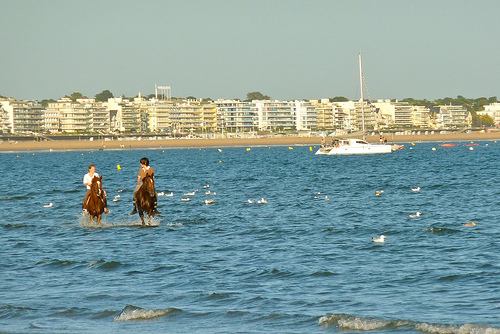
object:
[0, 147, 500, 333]
water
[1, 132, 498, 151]
beach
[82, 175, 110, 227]
horse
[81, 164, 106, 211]
person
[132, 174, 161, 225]
horse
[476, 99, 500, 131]
buildings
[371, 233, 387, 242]
bird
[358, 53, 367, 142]
pole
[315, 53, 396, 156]
boat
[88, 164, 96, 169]
hair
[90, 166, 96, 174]
face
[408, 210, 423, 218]
bird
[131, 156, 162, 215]
person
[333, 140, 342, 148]
people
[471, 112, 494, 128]
trees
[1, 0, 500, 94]
sky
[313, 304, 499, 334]
waves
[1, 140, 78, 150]
sand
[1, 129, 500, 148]
shore